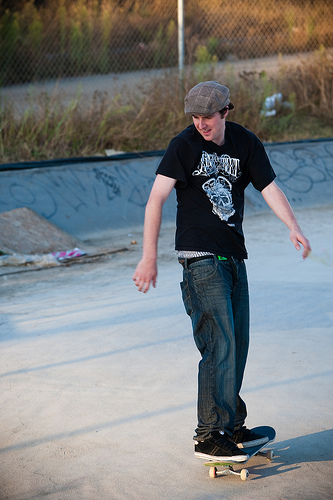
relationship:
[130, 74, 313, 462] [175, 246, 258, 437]
man wearing jeans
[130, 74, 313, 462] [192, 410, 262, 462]
man wearing shoes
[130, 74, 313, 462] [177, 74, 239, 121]
man wearing hat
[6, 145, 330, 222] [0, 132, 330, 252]
graffiti on concrete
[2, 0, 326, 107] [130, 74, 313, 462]
fence behind man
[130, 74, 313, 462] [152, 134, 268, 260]
man wearing t shirt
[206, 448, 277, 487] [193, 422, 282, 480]
wheels on skateboard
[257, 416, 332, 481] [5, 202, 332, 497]
shadows on ground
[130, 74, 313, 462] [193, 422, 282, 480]
man on skateboard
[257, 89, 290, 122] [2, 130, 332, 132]
trash on outskirts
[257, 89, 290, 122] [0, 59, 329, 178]
trash on roadside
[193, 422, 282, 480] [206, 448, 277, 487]
skateboard with wheels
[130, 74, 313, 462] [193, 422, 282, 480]
man riding skateboard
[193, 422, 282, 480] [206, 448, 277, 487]
skateboard has wheels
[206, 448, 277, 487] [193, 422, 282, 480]
wheels of skateboard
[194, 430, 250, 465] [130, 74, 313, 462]
foot of man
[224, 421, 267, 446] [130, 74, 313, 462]
foot of man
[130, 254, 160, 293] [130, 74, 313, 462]
hand of man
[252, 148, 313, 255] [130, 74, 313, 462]
arm of man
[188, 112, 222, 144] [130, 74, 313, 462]
face of man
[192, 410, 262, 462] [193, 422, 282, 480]
shoes riding skateboard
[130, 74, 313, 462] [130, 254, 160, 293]
man with hand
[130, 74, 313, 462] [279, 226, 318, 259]
man with hand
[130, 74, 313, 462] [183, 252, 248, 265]
man wearing belt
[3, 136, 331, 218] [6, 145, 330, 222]
graffiti on ramp